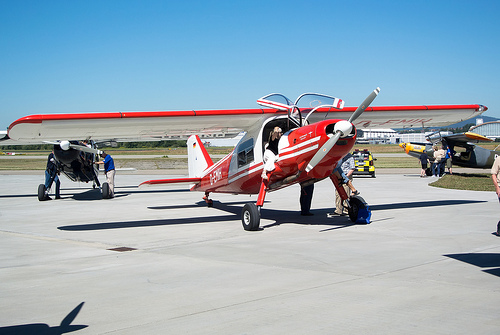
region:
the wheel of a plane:
[95, 176, 112, 198]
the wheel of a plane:
[32, 182, 51, 203]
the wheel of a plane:
[242, 202, 258, 232]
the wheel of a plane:
[341, 197, 365, 219]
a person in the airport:
[84, 137, 119, 204]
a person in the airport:
[36, 143, 68, 204]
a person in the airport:
[248, 109, 290, 183]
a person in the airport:
[318, 140, 361, 196]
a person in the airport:
[490, 153, 499, 230]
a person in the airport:
[294, 173, 321, 213]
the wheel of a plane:
[344, 195, 375, 232]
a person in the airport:
[259, 120, 281, 191]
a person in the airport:
[428, 141, 442, 183]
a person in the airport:
[411, 147, 429, 182]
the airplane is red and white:
[176, 58, 435, 243]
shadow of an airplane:
[11, 268, 117, 333]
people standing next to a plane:
[411, 126, 498, 187]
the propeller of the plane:
[303, 83, 384, 180]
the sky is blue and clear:
[84, 16, 465, 73]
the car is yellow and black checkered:
[351, 149, 385, 179]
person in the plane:
[248, 120, 296, 197]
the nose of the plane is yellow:
[382, 125, 437, 170]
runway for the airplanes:
[106, 142, 182, 170]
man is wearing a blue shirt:
[88, 148, 135, 177]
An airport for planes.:
[41, 106, 499, 226]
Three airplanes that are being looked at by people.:
[17, 74, 498, 224]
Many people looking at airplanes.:
[41, 115, 495, 204]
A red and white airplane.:
[16, 92, 487, 206]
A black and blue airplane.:
[25, 128, 106, 203]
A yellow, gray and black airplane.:
[400, 127, 488, 176]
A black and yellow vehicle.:
[334, 136, 387, 187]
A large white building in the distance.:
[125, 127, 453, 148]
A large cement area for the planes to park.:
[7, 168, 498, 299]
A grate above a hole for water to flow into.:
[106, 234, 141, 264]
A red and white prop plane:
[25, 80, 480, 223]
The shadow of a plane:
[108, 194, 423, 246]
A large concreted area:
[32, 203, 265, 318]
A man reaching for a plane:
[85, 142, 120, 196]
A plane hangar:
[459, 116, 493, 138]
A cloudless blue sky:
[60, 10, 228, 72]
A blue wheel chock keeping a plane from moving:
[345, 200, 380, 225]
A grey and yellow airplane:
[405, 120, 485, 170]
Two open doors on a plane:
[255, 87, 342, 144]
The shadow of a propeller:
[65, 292, 98, 333]